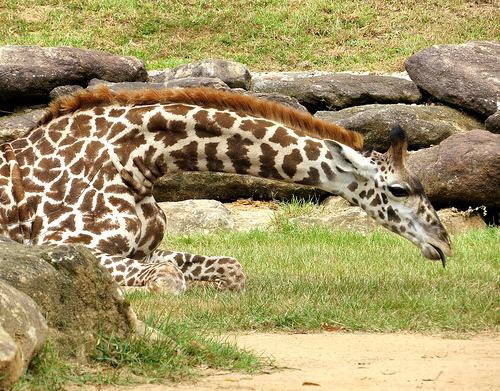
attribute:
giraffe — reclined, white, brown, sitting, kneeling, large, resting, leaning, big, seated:
[9, 84, 424, 274]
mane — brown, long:
[68, 83, 332, 129]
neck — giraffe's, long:
[126, 83, 356, 199]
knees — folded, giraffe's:
[170, 228, 285, 310]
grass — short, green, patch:
[197, 231, 365, 345]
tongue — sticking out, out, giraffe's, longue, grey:
[426, 245, 454, 268]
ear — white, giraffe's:
[320, 131, 375, 184]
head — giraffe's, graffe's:
[347, 128, 441, 258]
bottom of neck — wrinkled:
[116, 158, 186, 210]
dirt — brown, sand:
[244, 324, 439, 390]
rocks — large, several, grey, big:
[1, 232, 101, 312]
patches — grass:
[242, 217, 439, 317]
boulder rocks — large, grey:
[338, 43, 499, 177]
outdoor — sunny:
[3, 2, 494, 375]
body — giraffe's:
[1, 140, 158, 254]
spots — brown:
[144, 113, 190, 150]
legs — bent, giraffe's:
[153, 242, 259, 299]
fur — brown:
[53, 128, 139, 196]